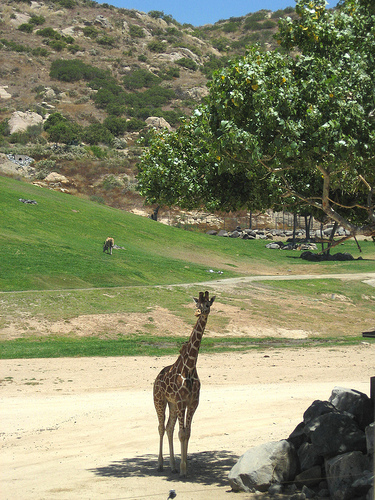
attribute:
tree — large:
[141, 0, 374, 235]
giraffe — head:
[153, 288, 217, 477]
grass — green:
[29, 184, 219, 291]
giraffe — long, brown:
[153, 248, 235, 468]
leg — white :
[175, 400, 186, 475]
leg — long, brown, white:
[186, 404, 201, 460]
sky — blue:
[96, 0, 351, 28]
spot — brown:
[178, 336, 192, 355]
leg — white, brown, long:
[173, 400, 189, 479]